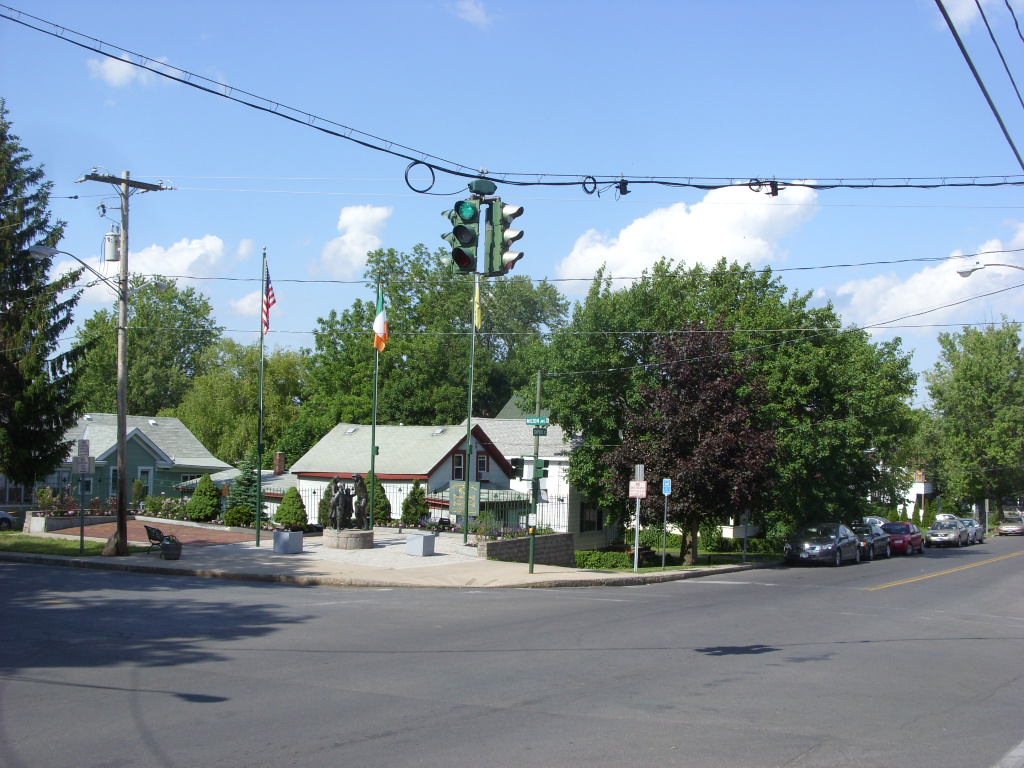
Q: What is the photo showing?
A: It is showing a street.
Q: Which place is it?
A: It is a street.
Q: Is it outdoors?
A: Yes, it is outdoors.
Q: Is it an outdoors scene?
A: Yes, it is outdoors.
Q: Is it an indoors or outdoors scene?
A: It is outdoors.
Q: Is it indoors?
A: No, it is outdoors.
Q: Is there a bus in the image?
A: No, there are no buses.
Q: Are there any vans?
A: No, there are no vans.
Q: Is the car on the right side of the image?
A: Yes, the car is on the right of the image.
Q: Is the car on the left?
A: No, the car is on the right of the image.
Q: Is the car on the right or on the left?
A: The car is on the right of the image.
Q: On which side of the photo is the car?
A: The car is on the right of the image.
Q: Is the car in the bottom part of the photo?
A: Yes, the car is in the bottom of the image.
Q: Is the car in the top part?
A: No, the car is in the bottom of the image.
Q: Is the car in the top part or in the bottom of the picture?
A: The car is in the bottom of the image.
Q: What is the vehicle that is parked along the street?
A: The vehicle is a car.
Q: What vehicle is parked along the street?
A: The vehicle is a car.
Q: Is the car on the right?
A: Yes, the car is on the right of the image.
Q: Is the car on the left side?
A: No, the car is on the right of the image.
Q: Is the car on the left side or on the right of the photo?
A: The car is on the right of the image.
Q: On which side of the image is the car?
A: The car is on the right of the image.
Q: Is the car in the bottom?
A: Yes, the car is in the bottom of the image.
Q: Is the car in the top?
A: No, the car is in the bottom of the image.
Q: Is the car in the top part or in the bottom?
A: The car is in the bottom of the image.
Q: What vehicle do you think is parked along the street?
A: The vehicle is a car.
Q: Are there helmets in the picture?
A: No, there are no helmets.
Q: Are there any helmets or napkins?
A: No, there are no helmets or napkins.